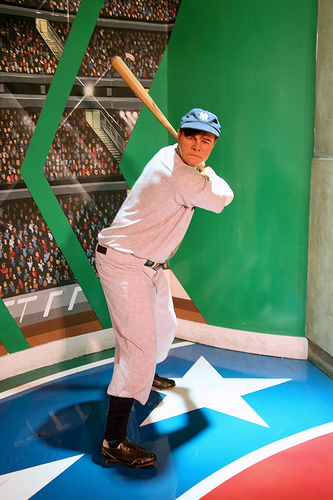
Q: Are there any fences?
A: No, there are no fences.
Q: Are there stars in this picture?
A: Yes, there is a star.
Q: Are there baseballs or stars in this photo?
A: Yes, there is a star.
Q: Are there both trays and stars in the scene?
A: No, there is a star but no trays.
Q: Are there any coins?
A: No, there are no coins.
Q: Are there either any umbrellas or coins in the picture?
A: No, there are no coins or umbrellas.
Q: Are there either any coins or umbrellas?
A: No, there are no coins or umbrellas.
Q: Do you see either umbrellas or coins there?
A: No, there are no coins or umbrellas.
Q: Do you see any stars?
A: Yes, there is a star.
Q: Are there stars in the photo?
A: Yes, there is a star.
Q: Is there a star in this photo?
A: Yes, there is a star.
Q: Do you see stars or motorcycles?
A: Yes, there is a star.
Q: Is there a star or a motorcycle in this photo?
A: Yes, there is a star.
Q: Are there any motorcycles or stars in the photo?
A: Yes, there is a star.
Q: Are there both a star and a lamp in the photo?
A: No, there is a star but no lamps.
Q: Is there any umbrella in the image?
A: No, there are no umbrellas.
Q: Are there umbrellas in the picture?
A: No, there are no umbrellas.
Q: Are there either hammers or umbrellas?
A: No, there are no umbrellas or hammers.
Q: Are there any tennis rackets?
A: No, there are no tennis rackets.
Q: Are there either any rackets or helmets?
A: No, there are no rackets or helmets.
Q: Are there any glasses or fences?
A: No, there are no fences or glasses.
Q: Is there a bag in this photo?
A: No, there are no bags.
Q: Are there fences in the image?
A: No, there are no fences.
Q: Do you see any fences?
A: No, there are no fences.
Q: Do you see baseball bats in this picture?
A: Yes, there is a baseball bat.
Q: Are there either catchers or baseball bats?
A: Yes, there is a baseball bat.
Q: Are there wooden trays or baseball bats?
A: Yes, there is a wood baseball bat.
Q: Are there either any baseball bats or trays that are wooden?
A: Yes, the baseball bat is wooden.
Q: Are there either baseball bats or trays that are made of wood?
A: Yes, the baseball bat is made of wood.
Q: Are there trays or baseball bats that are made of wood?
A: Yes, the baseball bat is made of wood.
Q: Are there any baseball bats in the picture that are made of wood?
A: Yes, there is a baseball bat that is made of wood.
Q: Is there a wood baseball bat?
A: Yes, there is a baseball bat that is made of wood.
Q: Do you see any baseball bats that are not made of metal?
A: Yes, there is a baseball bat that is made of wood.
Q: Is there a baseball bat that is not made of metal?
A: Yes, there is a baseball bat that is made of wood.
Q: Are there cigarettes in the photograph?
A: No, there are no cigarettes.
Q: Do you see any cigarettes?
A: No, there are no cigarettes.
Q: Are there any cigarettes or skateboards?
A: No, there are no cigarettes or skateboards.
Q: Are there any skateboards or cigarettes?
A: No, there are no cigarettes or skateboards.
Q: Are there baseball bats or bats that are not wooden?
A: No, there is a baseball bat but it is wooden.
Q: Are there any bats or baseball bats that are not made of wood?
A: No, there is a baseball bat but it is made of wood.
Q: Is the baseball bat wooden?
A: Yes, the baseball bat is wooden.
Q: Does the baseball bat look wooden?
A: Yes, the baseball bat is wooden.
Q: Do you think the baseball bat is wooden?
A: Yes, the baseball bat is wooden.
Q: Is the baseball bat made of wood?
A: Yes, the baseball bat is made of wood.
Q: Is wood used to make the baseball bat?
A: Yes, the baseball bat is made of wood.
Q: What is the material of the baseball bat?
A: The baseball bat is made of wood.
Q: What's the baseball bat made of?
A: The baseball bat is made of wood.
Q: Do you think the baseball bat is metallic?
A: No, the baseball bat is wooden.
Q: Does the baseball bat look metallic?
A: No, the baseball bat is wooden.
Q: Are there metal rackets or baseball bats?
A: No, there is a baseball bat but it is wooden.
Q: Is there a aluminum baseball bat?
A: No, there is a baseball bat but it is made of wood.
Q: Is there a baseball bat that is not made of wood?
A: No, there is a baseball bat but it is made of wood.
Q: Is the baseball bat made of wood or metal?
A: The baseball bat is made of wood.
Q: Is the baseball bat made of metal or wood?
A: The baseball bat is made of wood.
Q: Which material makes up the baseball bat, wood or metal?
A: The baseball bat is made of wood.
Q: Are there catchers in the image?
A: No, there are no catchers.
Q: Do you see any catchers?
A: No, there are no catchers.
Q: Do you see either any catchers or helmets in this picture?
A: No, there are no catchers or helmets.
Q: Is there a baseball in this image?
A: Yes, there is a baseball.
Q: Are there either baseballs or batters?
A: Yes, there is a baseball.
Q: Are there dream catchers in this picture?
A: No, there are no dream catchers.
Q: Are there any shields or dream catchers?
A: No, there are no dream catchers or shields.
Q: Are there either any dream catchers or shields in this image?
A: No, there are no dream catchers or shields.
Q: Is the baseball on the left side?
A: Yes, the baseball is on the left of the image.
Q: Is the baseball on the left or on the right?
A: The baseball is on the left of the image.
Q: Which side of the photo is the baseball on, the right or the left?
A: The baseball is on the left of the image.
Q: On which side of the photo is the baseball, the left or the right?
A: The baseball is on the left of the image.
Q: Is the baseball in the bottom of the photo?
A: No, the baseball is in the top of the image.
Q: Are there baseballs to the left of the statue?
A: Yes, there is a baseball to the left of the statue.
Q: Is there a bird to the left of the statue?
A: No, there is a baseball to the left of the statue.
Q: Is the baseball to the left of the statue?
A: Yes, the baseball is to the left of the statue.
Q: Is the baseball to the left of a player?
A: No, the baseball is to the left of the statue.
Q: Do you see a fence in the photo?
A: No, there are no fences.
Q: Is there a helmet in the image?
A: No, there are no helmets.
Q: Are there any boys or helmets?
A: No, there are no helmets or boys.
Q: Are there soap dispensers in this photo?
A: No, there are no soap dispensers.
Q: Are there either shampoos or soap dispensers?
A: No, there are no soap dispensers or shampoos.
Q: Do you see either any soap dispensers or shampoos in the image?
A: No, there are no soap dispensers or shampoos.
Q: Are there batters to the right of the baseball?
A: No, there is a statue to the right of the baseball.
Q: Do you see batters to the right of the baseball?
A: No, there is a statue to the right of the baseball.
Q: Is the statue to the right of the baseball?
A: Yes, the statue is to the right of the baseball.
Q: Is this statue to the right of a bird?
A: No, the statue is to the right of the baseball.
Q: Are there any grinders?
A: No, there are no grinders.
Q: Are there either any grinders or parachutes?
A: No, there are no grinders or parachutes.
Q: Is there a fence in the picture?
A: No, there are no fences.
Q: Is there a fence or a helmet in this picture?
A: No, there are no fences or helmets.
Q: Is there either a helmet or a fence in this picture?
A: No, there are no fences or helmets.